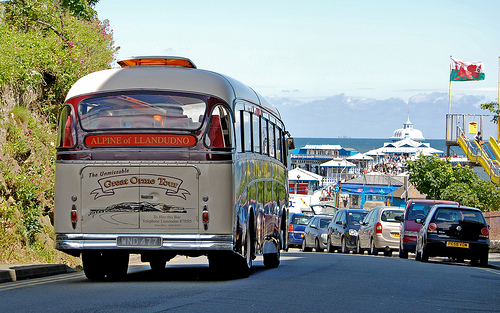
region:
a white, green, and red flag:
[446, 54, 486, 84]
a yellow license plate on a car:
[442, 239, 472, 251]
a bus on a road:
[53, 55, 294, 281]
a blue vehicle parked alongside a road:
[285, 211, 313, 246]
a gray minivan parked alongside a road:
[354, 204, 407, 253]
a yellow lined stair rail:
[456, 124, 498, 179]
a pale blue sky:
[96, 1, 498, 101]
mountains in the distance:
[280, 93, 498, 134]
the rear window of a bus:
[76, 93, 208, 133]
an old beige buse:
[52, 54, 294, 268]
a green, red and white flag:
[447, 53, 487, 82]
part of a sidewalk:
[486, 246, 498, 267]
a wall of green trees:
[0, 3, 112, 85]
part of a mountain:
[266, 93, 488, 138]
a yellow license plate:
[446, 235, 471, 249]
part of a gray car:
[357, 204, 400, 251]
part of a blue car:
[285, 212, 311, 245]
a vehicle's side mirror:
[390, 213, 405, 222]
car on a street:
[416, 200, 496, 260]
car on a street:
[400, 191, 415, 241]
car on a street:
[330, 201, 356, 241]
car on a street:
[300, 215, 330, 248]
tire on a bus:
[201, 225, 267, 275]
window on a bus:
[66, 93, 214, 143]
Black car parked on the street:
[418, 191, 490, 263]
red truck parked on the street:
[405, 190, 458, 245]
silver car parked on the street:
[361, 195, 408, 251]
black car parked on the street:
[333, 201, 362, 252]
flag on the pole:
[441, 58, 488, 84]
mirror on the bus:
[276, 122, 297, 156]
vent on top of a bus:
[103, 35, 188, 80]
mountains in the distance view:
[318, 82, 472, 133]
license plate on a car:
[446, 235, 473, 252]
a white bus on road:
[55, 54, 292, 281]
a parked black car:
[416, 204, 488, 267]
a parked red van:
[400, 199, 460, 259]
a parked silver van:
[357, 206, 407, 254]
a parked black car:
[327, 208, 366, 251]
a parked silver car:
[302, 213, 329, 252]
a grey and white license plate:
[116, 235, 160, 246]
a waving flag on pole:
[448, 54, 485, 114]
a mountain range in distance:
[268, 92, 498, 137]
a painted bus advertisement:
[81, 166, 197, 231]